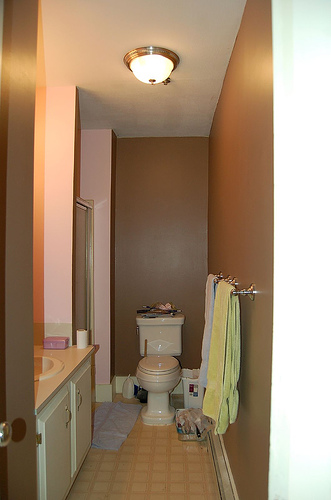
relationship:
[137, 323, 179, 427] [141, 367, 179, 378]
toilet has seat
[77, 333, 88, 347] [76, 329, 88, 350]
roll of roll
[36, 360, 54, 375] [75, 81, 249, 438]
sink in bathroom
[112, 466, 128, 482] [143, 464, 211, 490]
pattern on floor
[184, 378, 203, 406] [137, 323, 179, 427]
trashcan next to toilet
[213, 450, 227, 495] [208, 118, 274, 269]
trim on wall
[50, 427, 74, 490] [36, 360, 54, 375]
cabinet under sink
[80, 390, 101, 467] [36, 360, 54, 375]
cabinet under sink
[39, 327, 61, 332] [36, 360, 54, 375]
trim by sink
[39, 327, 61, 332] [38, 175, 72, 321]
trim on wall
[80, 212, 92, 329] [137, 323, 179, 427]
shower next to toilet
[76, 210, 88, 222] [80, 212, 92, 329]
door of shower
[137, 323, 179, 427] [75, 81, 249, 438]
toilet in bathroom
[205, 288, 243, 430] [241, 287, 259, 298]
towel on towel rack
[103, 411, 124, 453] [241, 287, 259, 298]
towel on towel rack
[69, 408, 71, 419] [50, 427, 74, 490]
handle on cabinet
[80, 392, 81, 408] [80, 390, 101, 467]
handle on cabinet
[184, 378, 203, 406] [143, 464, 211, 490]
trashcan on floor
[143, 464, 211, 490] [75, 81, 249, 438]
floor of bathroom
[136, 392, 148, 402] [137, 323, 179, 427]
plunger next to toilet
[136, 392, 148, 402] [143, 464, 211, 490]
plunger on floor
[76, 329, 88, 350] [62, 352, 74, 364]
roll on counter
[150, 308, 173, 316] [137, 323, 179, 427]
curling iron on toilet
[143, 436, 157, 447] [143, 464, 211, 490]
tile on floor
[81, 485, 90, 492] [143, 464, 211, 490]
tile on floor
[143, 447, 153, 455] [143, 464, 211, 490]
tile on floor